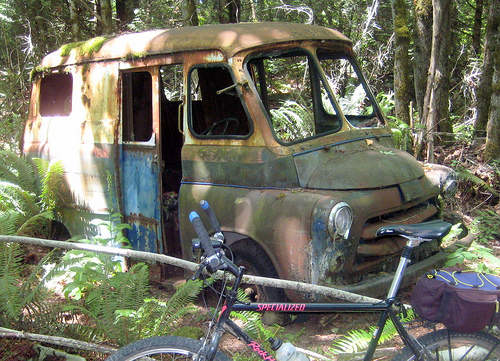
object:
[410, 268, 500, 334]
bag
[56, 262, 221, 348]
plant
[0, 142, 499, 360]
ground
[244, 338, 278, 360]
words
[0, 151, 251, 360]
forest shrubbery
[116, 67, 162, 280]
door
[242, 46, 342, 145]
window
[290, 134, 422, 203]
hood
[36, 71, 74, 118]
window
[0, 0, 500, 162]
tree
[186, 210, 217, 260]
handle bars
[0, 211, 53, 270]
branch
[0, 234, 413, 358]
fence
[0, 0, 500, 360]
scene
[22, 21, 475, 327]
car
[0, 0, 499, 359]
woods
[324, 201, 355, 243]
head light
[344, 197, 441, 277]
grill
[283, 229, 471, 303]
bumper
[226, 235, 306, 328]
wheel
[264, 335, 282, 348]
lid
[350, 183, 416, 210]
area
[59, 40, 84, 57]
moss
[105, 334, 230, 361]
tire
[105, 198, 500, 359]
bicycle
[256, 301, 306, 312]
writing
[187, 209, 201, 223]
end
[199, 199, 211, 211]
end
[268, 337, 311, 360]
bottle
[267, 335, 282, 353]
top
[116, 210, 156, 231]
rust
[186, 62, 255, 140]
window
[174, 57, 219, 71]
rust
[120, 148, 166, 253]
paint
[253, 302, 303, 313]
specialized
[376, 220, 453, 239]
seat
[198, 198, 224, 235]
handlebars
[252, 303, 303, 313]
paint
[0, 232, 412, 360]
gate